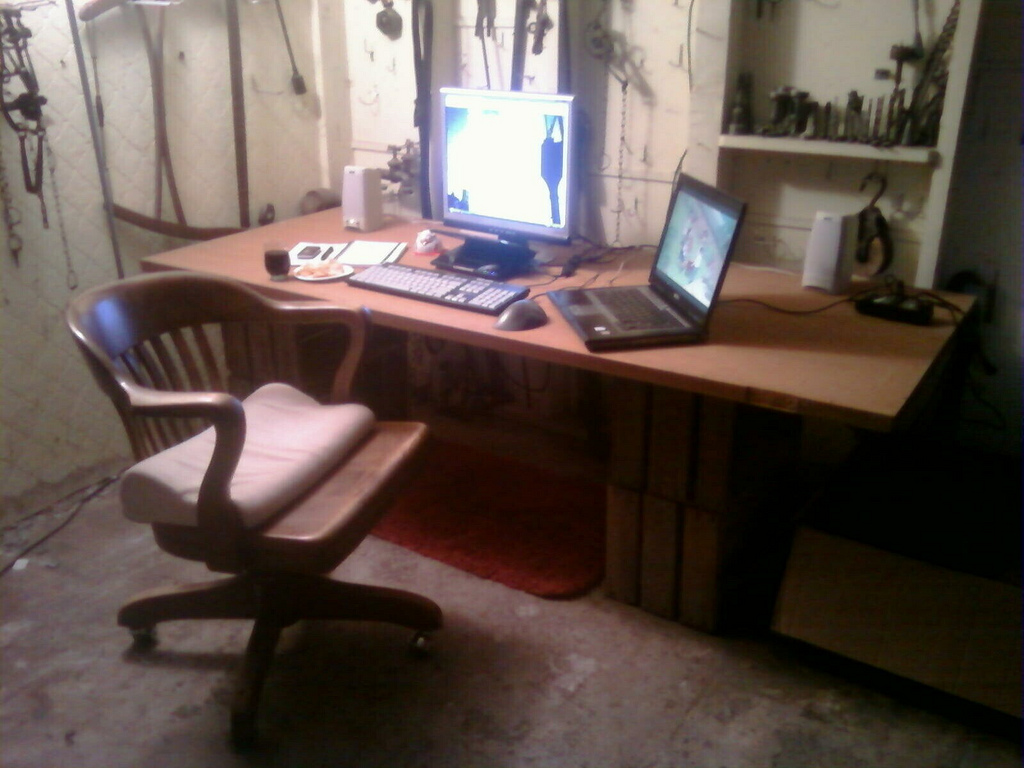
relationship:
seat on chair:
[140, 365, 352, 530] [61, 261, 455, 752]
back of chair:
[69, 297, 318, 403] [75, 273, 519, 764]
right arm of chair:
[118, 381, 255, 509] [75, 273, 519, 764]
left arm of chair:
[246, 284, 413, 440] [68, 258, 501, 742]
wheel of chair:
[125, 620, 180, 666] [68, 258, 501, 742]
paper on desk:
[295, 237, 412, 287] [130, 194, 993, 668]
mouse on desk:
[500, 294, 555, 349] [130, 194, 993, 668]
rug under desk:
[321, 421, 615, 622] [130, 194, 993, 668]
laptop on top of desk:
[541, 177, 753, 385] [130, 194, 993, 668]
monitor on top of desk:
[414, 97, 603, 251] [130, 194, 993, 668]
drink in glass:
[273, 251, 280, 264] [262, 246, 306, 294]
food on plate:
[301, 259, 332, 279] [284, 257, 358, 281]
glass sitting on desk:
[256, 238, 298, 278] [131, 194, 986, 636]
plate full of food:
[291, 259, 352, 288] [286, 266, 330, 282]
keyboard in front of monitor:
[345, 259, 533, 327] [420, 103, 600, 246]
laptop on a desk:
[545, 171, 752, 350] [130, 194, 993, 668]